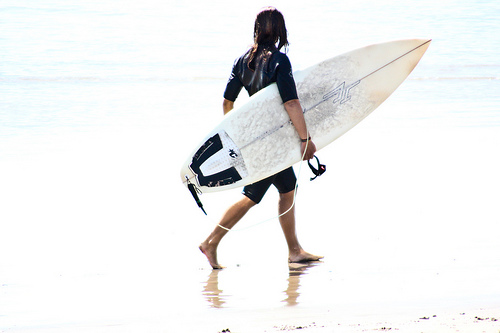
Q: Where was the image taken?
A: It was taken at the beach.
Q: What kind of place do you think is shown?
A: It is a beach.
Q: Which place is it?
A: It is a beach.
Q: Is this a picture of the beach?
A: Yes, it is showing the beach.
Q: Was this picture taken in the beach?
A: Yes, it was taken in the beach.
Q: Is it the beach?
A: Yes, it is the beach.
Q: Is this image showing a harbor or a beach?
A: It is showing a beach.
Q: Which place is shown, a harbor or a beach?
A: It is a beach.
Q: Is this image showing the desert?
A: No, the picture is showing the beach.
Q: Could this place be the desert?
A: No, it is the beach.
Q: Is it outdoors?
A: Yes, it is outdoors.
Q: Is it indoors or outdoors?
A: It is outdoors.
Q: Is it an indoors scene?
A: No, it is outdoors.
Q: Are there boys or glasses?
A: No, there are no boys or glasses.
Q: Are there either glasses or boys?
A: No, there are no boys or glasses.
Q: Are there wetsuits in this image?
A: Yes, there is a wetsuit.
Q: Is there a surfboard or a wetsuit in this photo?
A: Yes, there is a wetsuit.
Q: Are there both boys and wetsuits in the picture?
A: No, there is a wetsuit but no boys.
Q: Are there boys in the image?
A: No, there are no boys.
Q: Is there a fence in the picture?
A: No, there are no fences.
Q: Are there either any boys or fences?
A: No, there are no fences or boys.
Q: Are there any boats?
A: No, there are no boats.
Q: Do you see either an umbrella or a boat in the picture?
A: No, there are no boats or umbrellas.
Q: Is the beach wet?
A: Yes, the beach is wet.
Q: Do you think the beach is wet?
A: Yes, the beach is wet.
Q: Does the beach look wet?
A: Yes, the beach is wet.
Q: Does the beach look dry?
A: No, the beach is wet.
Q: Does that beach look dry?
A: No, the beach is wet.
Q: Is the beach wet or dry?
A: The beach is wet.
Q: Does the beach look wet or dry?
A: The beach is wet.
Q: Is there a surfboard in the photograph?
A: Yes, there is a surfboard.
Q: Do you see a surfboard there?
A: Yes, there is a surfboard.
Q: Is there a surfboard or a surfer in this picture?
A: Yes, there is a surfboard.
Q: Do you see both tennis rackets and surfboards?
A: No, there is a surfboard but no rackets.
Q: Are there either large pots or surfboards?
A: Yes, there is a large surfboard.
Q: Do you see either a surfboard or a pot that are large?
A: Yes, the surfboard is large.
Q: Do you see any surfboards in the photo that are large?
A: Yes, there is a large surfboard.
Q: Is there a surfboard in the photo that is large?
A: Yes, there is a surfboard that is large.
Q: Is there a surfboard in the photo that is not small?
A: Yes, there is a large surfboard.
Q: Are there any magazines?
A: No, there are no magazines.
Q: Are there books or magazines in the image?
A: No, there are no magazines or books.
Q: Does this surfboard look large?
A: Yes, the surfboard is large.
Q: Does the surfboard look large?
A: Yes, the surfboard is large.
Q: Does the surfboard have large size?
A: Yes, the surfboard is large.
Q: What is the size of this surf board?
A: The surf board is large.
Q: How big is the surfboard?
A: The surfboard is large.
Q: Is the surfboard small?
A: No, the surfboard is large.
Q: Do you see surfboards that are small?
A: No, there is a surfboard but it is large.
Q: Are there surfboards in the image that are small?
A: No, there is a surfboard but it is large.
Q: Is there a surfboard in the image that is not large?
A: No, there is a surfboard but it is large.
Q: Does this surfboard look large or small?
A: The surfboard is large.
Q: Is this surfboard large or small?
A: The surfboard is large.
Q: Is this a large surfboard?
A: Yes, this is a large surfboard.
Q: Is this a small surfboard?
A: No, this is a large surfboard.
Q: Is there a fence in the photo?
A: No, there are no fences.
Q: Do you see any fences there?
A: No, there are no fences.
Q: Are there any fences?
A: No, there are no fences.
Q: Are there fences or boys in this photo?
A: No, there are no fences or boys.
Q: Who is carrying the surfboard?
A: The guy is carrying the surfboard.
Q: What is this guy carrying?
A: The guy is carrying a surf board.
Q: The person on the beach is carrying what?
A: The guy is carrying a surf board.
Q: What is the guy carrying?
A: The guy is carrying a surf board.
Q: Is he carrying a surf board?
A: Yes, the guy is carrying a surf board.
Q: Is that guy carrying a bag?
A: No, the guy is carrying a surf board.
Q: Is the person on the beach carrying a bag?
A: No, the guy is carrying a surf board.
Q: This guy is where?
A: The guy is on the beach.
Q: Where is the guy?
A: The guy is on the beach.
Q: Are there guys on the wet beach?
A: Yes, there is a guy on the beach.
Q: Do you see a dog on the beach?
A: No, there is a guy on the beach.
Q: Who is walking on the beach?
A: The guy is walking on the beach.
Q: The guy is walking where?
A: The guy is walking on the beach.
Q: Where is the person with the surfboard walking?
A: The guy is walking on the beach.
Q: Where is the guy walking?
A: The guy is walking on the beach.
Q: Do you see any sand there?
A: Yes, there is sand.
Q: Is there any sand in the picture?
A: Yes, there is sand.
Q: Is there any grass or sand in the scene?
A: Yes, there is sand.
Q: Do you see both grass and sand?
A: No, there is sand but no grass.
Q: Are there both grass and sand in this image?
A: No, there is sand but no grass.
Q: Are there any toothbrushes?
A: No, there are no toothbrushes.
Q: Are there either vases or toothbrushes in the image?
A: No, there are no toothbrushes or vases.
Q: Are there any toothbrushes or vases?
A: No, there are no toothbrushes or vases.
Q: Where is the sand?
A: The sand is on the beach.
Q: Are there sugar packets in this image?
A: No, there are no sugar packets.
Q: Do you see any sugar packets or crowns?
A: No, there are no sugar packets or crowns.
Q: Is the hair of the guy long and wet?
A: Yes, the hair is long and wet.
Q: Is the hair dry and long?
A: No, the hair is long but wet.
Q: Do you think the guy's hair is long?
A: Yes, the hair is long.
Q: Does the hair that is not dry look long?
A: Yes, the hair is long.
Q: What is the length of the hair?
A: The hair is long.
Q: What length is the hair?
A: The hair is long.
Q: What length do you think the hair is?
A: The hair is long.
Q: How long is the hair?
A: The hair is long.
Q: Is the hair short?
A: No, the hair is long.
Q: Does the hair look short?
A: No, the hair is long.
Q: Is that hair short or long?
A: The hair is long.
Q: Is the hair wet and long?
A: Yes, the hair is wet and long.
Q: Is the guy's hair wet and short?
A: No, the hair is wet but long.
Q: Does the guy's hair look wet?
A: Yes, the hair is wet.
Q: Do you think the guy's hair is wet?
A: Yes, the hair is wet.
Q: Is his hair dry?
A: No, the hair is wet.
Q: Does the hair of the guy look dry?
A: No, the hair is wet.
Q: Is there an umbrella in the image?
A: No, there are no umbrellas.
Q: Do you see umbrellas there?
A: No, there are no umbrellas.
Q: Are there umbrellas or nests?
A: No, there are no umbrellas or nests.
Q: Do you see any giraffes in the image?
A: No, there are no giraffes.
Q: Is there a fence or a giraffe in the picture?
A: No, there are no giraffes or fences.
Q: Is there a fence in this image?
A: No, there are no fences.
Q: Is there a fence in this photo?
A: No, there are no fences.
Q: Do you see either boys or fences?
A: No, there are no fences or boys.